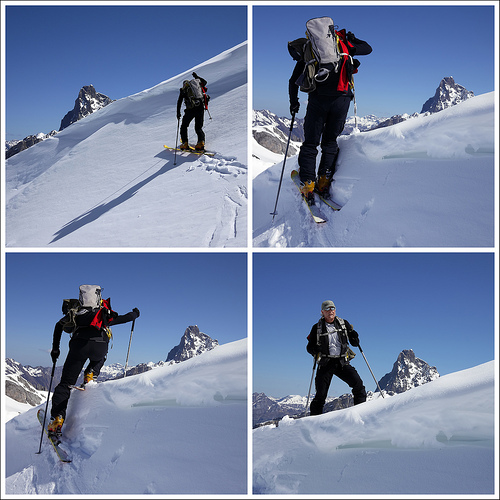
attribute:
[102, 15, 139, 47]
sky — blue, daytime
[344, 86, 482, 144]
patches — snow